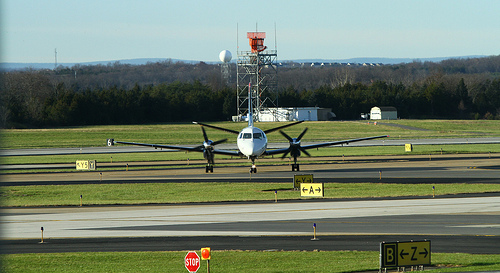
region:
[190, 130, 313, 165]
the planes propellers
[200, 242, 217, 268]
red light on the grass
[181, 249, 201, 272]
a red stop sign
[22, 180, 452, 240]
lights on the runway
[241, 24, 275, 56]
a satelitte on the tower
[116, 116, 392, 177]
a white twin propeller plane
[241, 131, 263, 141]
the windshield for the plane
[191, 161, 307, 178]
wheels on the ground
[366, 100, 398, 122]
a white barn in the field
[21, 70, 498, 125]
Trees behind the buildings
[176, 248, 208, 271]
red stop sign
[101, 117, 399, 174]
airplane on taxi way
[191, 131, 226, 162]
propeller of airplane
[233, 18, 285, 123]
radio tower in background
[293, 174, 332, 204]
yellow and black sign with A and arrows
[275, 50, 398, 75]
buildings in far background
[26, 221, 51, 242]
beacon lights on runway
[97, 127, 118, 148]
sign with number six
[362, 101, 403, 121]
barn style building in background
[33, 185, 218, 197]
grassy area between taxi ways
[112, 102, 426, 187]
Plane sitting on runway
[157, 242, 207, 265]
Stop sign is red and white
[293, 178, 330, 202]
Yellow and black sign on runway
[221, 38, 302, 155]
Tower behind the plane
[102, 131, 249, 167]
Long wing on the plane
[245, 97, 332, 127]
Building in the background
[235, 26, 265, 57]
Control tower building is red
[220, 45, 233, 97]
White water tower in the background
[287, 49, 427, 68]
Mountains behind the wooded area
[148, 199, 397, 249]
Pavement in front of the plane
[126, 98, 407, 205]
Plan on the runway.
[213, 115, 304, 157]
Window on the plane.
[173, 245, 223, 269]
Stop sign on the grass.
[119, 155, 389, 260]
Runway under the plane.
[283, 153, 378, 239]
Sign on the road.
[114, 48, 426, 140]
Trees in the background.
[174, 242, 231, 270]
Red stop sign on the road.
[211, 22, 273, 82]
Tower in the background.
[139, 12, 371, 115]
Blue sky behind the trees.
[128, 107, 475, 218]
Wings on the plane.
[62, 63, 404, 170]
parked single small plane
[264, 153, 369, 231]
small yellow sign with a bold A and directional arrows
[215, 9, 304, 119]
small steel communications tower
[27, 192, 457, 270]
runway of airport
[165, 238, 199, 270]
red octagonal stop sign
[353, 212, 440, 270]
yellow sign with black painted square and yellow B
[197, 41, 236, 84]
large white water tower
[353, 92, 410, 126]
small hanger in field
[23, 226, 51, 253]
runway markers at small airport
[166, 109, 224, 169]
propeller on a plane